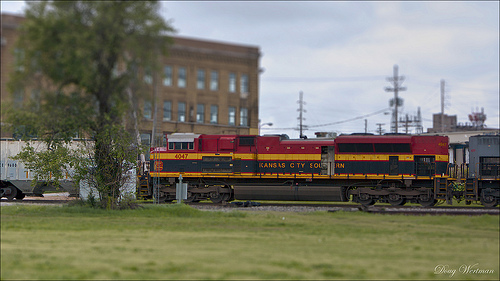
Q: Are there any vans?
A: No, there are no vans.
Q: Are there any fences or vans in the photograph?
A: No, there are no vans or fences.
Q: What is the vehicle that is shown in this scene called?
A: The vehicle is a car.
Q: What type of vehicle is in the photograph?
A: The vehicle is a car.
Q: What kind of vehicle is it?
A: The vehicle is a car.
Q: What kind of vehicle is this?
A: This is a car.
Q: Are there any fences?
A: No, there are no fences.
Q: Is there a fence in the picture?
A: No, there are no fences.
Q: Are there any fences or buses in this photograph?
A: No, there are no fences or buses.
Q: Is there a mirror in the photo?
A: No, there are no mirrors.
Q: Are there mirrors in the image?
A: No, there are no mirrors.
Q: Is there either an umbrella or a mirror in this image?
A: No, there are no mirrors or umbrellas.